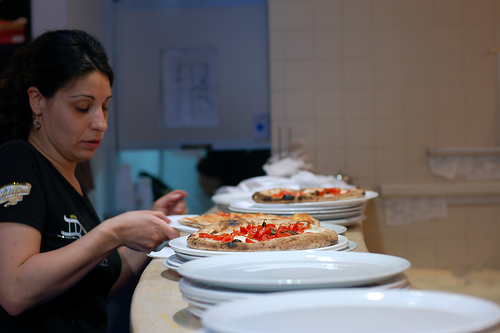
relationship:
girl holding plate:
[0, 27, 187, 332] [163, 208, 347, 238]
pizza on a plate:
[193, 225, 333, 245] [167, 234, 355, 257]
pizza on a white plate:
[185, 216, 338, 249] [167, 226, 354, 259]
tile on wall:
[311, 115, 348, 149] [272, 0, 497, 270]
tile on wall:
[341, 84, 378, 119] [272, 0, 497, 270]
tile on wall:
[340, 55, 377, 92] [272, 0, 497, 270]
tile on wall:
[279, 23, 314, 63] [272, 0, 497, 270]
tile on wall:
[340, 27, 375, 62] [272, 0, 497, 270]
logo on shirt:
[0, 181, 34, 211] [0, 139, 124, 332]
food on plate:
[179, 207, 317, 231] [162, 205, 346, 245]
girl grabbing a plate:
[0, 27, 187, 332] [162, 205, 346, 245]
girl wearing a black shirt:
[0, 27, 187, 332] [11, 147, 126, 327]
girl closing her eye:
[0, 27, 187, 332] [74, 100, 90, 113]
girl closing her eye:
[0, 27, 187, 332] [102, 105, 109, 110]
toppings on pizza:
[209, 221, 386, 269] [205, 215, 307, 243]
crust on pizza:
[190, 228, 339, 252] [187, 205, 347, 258]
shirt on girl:
[0, 139, 121, 330] [0, 27, 187, 332]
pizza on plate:
[185, 216, 338, 249] [159, 216, 349, 255]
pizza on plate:
[239, 168, 379, 221] [212, 188, 389, 218]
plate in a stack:
[250, 197, 377, 207] [211, 190, 256, 212]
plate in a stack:
[163, 213, 348, 235] [228, 191, 378, 226]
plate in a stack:
[167, 234, 349, 257] [162, 234, 358, 271]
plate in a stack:
[177, 249, 412, 291] [176, 251, 411, 321]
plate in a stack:
[202, 287, 499, 332] [202, 287, 497, 332]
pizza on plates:
[185, 216, 338, 249] [153, 135, 415, 232]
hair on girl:
[37, 45, 80, 67] [0, 27, 187, 332]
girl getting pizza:
[0, 27, 187, 332] [192, 215, 331, 260]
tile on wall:
[281, 11, 483, 245] [272, 0, 497, 270]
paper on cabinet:
[155, 42, 227, 130] [116, 5, 271, 147]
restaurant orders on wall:
[374, 135, 499, 230] [294, 2, 493, 121]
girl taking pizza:
[0, 29, 186, 331] [173, 209, 243, 227]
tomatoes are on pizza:
[244, 224, 294, 240] [185, 219, 339, 251]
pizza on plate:
[185, 216, 338, 249] [163, 222, 363, 260]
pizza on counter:
[185, 216, 338, 249] [124, 176, 419, 329]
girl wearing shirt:
[0, 27, 187, 332] [12, 148, 121, 305]